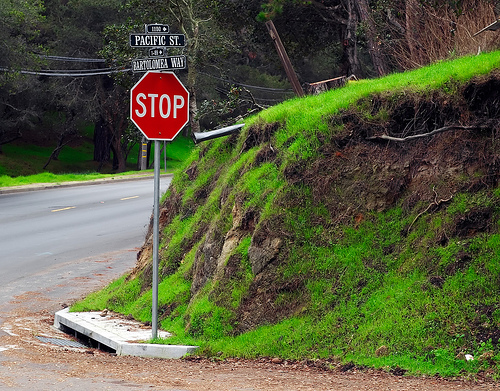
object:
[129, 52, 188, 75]
sign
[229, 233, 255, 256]
moss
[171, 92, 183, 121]
letters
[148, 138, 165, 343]
pole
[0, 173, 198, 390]
road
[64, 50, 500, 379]
hill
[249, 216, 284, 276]
rocks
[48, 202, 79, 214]
lines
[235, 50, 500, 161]
grass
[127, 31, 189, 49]
pacific street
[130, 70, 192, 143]
stop sign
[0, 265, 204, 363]
street corner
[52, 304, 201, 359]
gutter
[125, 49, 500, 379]
bank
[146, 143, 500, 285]
hill side